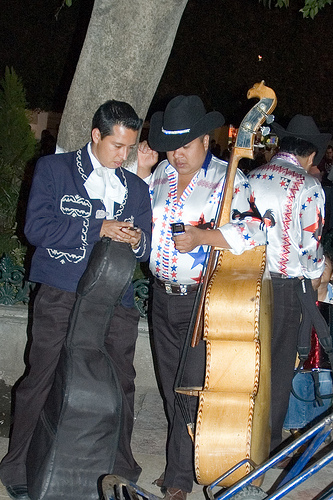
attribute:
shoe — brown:
[151, 471, 166, 487]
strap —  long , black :
[297, 278, 331, 363]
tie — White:
[79, 171, 123, 209]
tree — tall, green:
[3, 65, 47, 268]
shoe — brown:
[151, 473, 185, 499]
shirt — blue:
[22, 141, 152, 310]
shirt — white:
[137, 152, 268, 287]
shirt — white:
[243, 151, 326, 278]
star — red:
[306, 195, 313, 206]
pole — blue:
[213, 408, 331, 498]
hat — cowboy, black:
[120, 75, 223, 162]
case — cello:
[61, 239, 123, 499]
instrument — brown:
[180, 80, 297, 450]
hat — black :
[139, 92, 255, 167]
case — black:
[59, 234, 127, 498]